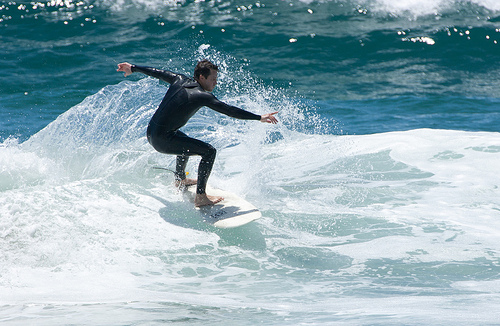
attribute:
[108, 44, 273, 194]
man — surfing, wet, balancing, talented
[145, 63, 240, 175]
wet suit — black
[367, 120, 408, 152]
water — blue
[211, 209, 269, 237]
board — white, wet